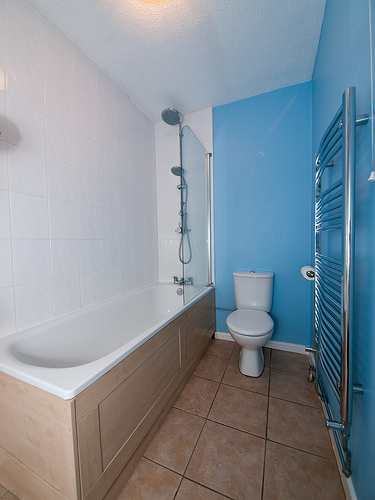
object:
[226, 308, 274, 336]
lid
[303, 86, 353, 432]
framework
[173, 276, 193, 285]
faucet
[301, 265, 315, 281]
paper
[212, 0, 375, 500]
wall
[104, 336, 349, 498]
flooring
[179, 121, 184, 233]
showerhead body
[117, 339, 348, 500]
tiles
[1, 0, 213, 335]
wall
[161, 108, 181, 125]
shower head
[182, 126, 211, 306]
glass wall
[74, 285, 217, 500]
wood portion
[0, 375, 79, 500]
wood portion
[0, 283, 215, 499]
bath tub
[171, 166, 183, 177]
shower head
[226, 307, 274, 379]
toilet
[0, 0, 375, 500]
bathroom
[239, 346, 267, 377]
base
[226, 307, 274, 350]
seat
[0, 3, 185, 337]
tiles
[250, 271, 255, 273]
buttons